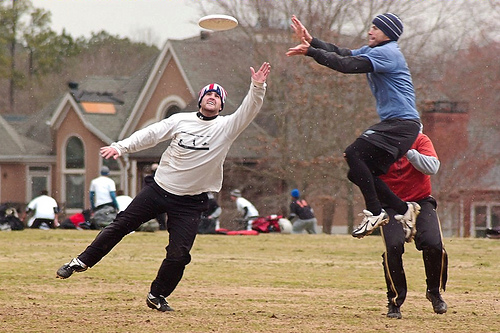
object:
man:
[55, 61, 273, 312]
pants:
[72, 184, 206, 299]